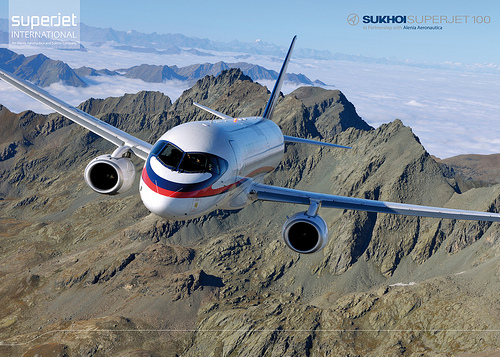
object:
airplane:
[0, 34, 500, 255]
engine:
[282, 210, 328, 254]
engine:
[83, 153, 136, 196]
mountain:
[0, 68, 500, 357]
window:
[157, 142, 214, 174]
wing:
[249, 180, 500, 222]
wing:
[0, 68, 153, 162]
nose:
[138, 158, 215, 221]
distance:
[0, 67, 499, 222]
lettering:
[361, 12, 493, 31]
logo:
[346, 13, 360, 26]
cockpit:
[154, 140, 223, 183]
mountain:
[0, 46, 87, 88]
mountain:
[120, 61, 329, 83]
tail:
[262, 34, 299, 120]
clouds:
[4, 27, 500, 163]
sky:
[0, 2, 260, 22]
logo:
[69, 105, 108, 126]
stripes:
[142, 165, 276, 198]